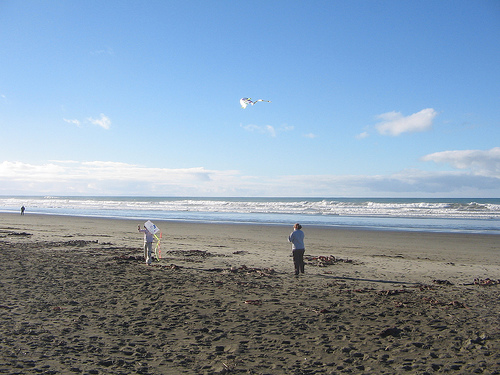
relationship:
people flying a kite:
[287, 222, 306, 276] [229, 82, 263, 123]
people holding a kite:
[287, 222, 306, 276] [145, 219, 162, 250]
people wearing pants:
[287, 222, 306, 276] [288, 246, 310, 280]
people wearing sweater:
[287, 222, 306, 276] [285, 229, 310, 251]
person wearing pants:
[130, 217, 170, 269] [138, 238, 158, 260]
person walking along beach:
[6, 197, 63, 260] [18, 151, 452, 371]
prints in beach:
[3, 237, 495, 373] [20, 180, 449, 374]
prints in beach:
[3, 237, 495, 373] [3, 191, 497, 372]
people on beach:
[285, 219, 312, 276] [4, 215, 494, 318]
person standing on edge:
[20, 205, 26, 216] [3, 208, 478, 273]